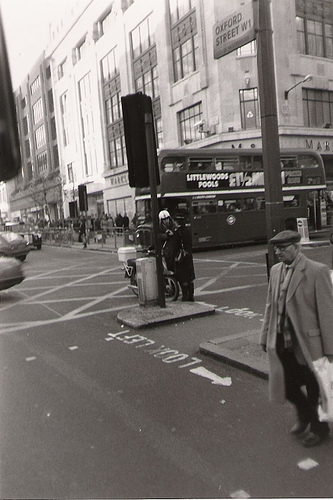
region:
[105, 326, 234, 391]
white print on a street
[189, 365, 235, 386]
arrow print on a street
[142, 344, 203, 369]
white print on a street reading LOOK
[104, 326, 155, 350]
white print on a street reading LEFT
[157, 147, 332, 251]
double decker bus on a street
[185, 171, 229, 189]
bold white print on a bus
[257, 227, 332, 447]
man walking on a street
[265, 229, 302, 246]
hat on a man's head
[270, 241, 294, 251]
glasses over a man's eyes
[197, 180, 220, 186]
white text on a bus ad reading POOLS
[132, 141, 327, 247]
double decker bus on city street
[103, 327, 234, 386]
words saying look left painted on street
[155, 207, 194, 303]
man and woman talking next to motorcycle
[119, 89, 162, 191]
traffic light seen from behind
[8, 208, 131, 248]
crowd of people on sidewalk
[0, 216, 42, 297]
cars lying on the street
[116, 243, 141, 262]
contained on the back of the motorcycle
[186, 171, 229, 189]
poster on bus advertising littlewoods pools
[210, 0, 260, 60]
signpost reading oxford street w1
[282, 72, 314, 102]
traffic lamp on side of building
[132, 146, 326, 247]
Large double decker bus.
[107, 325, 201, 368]
White letters on the road that say LOOK LEFT.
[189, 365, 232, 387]
Large thick white arrow on the road.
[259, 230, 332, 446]
An old man in a long coat with glasses holding a bag.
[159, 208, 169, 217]
A white helmet on a man's head.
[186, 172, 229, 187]
LITTLEWOODS POOLS on the side of a bus.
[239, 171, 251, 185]
White 1/2 on the side of a bus.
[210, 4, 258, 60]
OXFORD STREET W1 sign up on a pole.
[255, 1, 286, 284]
A black pole with an oxford sign on the top.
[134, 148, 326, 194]
The top deck of a double decker bus.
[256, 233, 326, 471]
man crossing the street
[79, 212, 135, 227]
people on the sidewalk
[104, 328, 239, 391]
white marks on the street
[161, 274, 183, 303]
rear tire of the bike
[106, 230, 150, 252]
corner of the street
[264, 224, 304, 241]
hat on the man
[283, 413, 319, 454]
shoes on the man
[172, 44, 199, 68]
window on the building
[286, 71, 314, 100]
light on side of building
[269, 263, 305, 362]
scarf around man's neck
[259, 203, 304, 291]
the head of a man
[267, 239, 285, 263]
the nose of a man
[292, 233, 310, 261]
the ear of a man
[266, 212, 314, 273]
a man wearing a hat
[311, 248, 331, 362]
the arm of a man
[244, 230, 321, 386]
a man wearing a coat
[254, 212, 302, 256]
a man wearing a hat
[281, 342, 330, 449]
the legs of a man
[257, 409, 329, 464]
the feet of a man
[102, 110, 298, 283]
a bus on the road